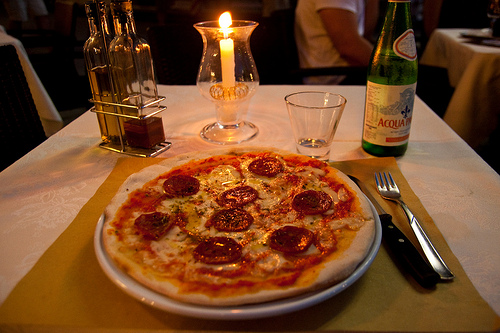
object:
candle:
[216, 11, 238, 123]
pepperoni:
[248, 157, 283, 177]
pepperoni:
[292, 190, 333, 215]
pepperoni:
[267, 225, 316, 254]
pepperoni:
[161, 173, 201, 200]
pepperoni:
[191, 235, 244, 265]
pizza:
[102, 143, 377, 307]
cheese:
[112, 154, 365, 292]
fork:
[372, 169, 455, 281]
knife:
[347, 174, 441, 286]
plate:
[93, 192, 384, 320]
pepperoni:
[209, 207, 254, 232]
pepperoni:
[220, 185, 260, 207]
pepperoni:
[132, 211, 176, 241]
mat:
[0, 155, 499, 332]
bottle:
[361, 0, 420, 158]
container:
[192, 19, 261, 145]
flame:
[216, 11, 234, 37]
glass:
[283, 91, 348, 163]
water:
[362, 48, 418, 156]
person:
[293, 0, 373, 85]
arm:
[314, 6, 375, 68]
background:
[0, 1, 499, 84]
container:
[108, 2, 167, 149]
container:
[81, 1, 129, 145]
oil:
[85, 67, 129, 146]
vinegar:
[124, 115, 168, 149]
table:
[419, 25, 499, 138]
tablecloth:
[0, 85, 499, 317]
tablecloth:
[427, 28, 499, 126]